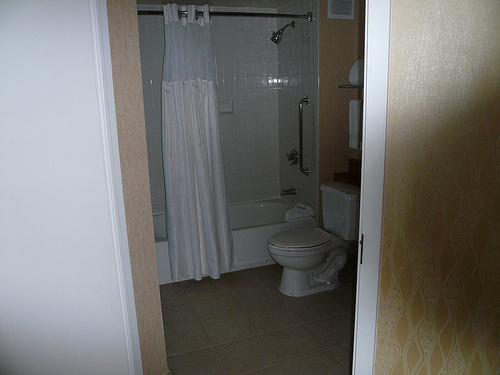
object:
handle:
[286, 95, 310, 177]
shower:
[138, 5, 321, 243]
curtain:
[160, 1, 234, 282]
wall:
[316, 0, 360, 232]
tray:
[218, 100, 234, 115]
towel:
[348, 99, 363, 150]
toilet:
[266, 226, 351, 297]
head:
[269, 22, 291, 45]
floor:
[157, 262, 356, 375]